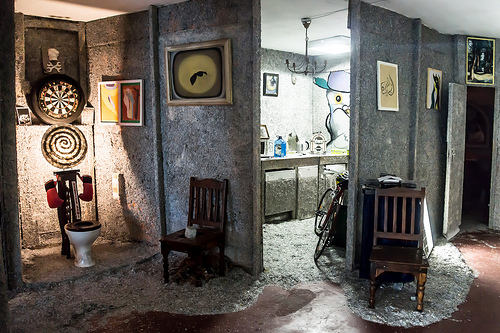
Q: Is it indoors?
A: Yes, it is indoors.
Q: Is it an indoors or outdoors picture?
A: It is indoors.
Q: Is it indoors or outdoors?
A: It is indoors.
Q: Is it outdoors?
A: No, it is indoors.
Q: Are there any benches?
A: No, there are no benches.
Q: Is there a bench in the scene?
A: No, there are no benches.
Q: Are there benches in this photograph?
A: No, there are no benches.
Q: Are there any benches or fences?
A: No, there are no benches or fences.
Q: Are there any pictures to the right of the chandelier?
A: Yes, there is a picture to the right of the chandelier.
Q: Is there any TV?
A: No, there are no televisions.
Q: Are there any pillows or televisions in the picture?
A: No, there are no televisions or pillows.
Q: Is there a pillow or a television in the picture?
A: No, there are no televisions or pillows.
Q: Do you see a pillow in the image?
A: No, there are no pillows.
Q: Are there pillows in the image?
A: No, there are no pillows.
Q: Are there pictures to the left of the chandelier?
A: Yes, there is a picture to the left of the chandelier.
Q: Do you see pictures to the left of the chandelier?
A: Yes, there is a picture to the left of the chandelier.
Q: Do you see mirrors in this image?
A: No, there are no mirrors.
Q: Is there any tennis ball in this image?
A: No, there are no tennis balls.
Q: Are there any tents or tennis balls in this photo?
A: No, there are no tennis balls or tents.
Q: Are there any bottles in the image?
A: Yes, there is a bottle.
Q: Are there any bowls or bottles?
A: Yes, there is a bottle.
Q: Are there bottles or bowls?
A: Yes, there is a bottle.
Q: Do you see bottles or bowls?
A: Yes, there is a bottle.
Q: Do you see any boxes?
A: No, there are no boxes.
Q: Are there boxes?
A: No, there are no boxes.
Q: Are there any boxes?
A: No, there are no boxes.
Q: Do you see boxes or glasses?
A: No, there are no boxes or glasses.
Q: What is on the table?
A: The bottle is on the table.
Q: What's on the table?
A: The bottle is on the table.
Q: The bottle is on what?
A: The bottle is on the table.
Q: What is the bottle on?
A: The bottle is on the table.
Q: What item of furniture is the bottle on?
A: The bottle is on the table.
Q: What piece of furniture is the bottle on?
A: The bottle is on the table.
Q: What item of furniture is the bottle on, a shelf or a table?
A: The bottle is on a table.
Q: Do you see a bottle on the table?
A: Yes, there is a bottle on the table.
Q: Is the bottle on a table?
A: Yes, the bottle is on a table.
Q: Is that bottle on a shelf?
A: No, the bottle is on a table.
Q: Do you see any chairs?
A: Yes, there is a chair.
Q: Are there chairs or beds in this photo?
A: Yes, there is a chair.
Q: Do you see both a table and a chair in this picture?
A: Yes, there are both a chair and a table.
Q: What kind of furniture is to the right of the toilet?
A: The piece of furniture is a chair.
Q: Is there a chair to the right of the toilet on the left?
A: Yes, there is a chair to the right of the toilet.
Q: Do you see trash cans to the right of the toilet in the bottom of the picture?
A: No, there is a chair to the right of the toilet.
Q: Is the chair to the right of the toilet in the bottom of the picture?
A: Yes, the chair is to the right of the toilet.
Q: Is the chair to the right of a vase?
A: No, the chair is to the right of the toilet.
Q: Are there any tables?
A: Yes, there is a table.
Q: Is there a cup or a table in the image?
A: Yes, there is a table.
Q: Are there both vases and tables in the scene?
A: No, there is a table but no vases.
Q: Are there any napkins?
A: No, there are no napkins.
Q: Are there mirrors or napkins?
A: No, there are no napkins or mirrors.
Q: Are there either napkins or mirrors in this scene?
A: No, there are no napkins or mirrors.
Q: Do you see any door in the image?
A: Yes, there is a door.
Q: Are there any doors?
A: Yes, there is a door.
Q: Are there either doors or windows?
A: Yes, there is a door.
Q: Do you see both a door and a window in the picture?
A: No, there is a door but no windows.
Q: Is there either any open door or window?
A: Yes, there is an open door.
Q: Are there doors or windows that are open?
A: Yes, the door is open.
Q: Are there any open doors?
A: Yes, there is an open door.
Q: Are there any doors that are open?
A: Yes, there is a door that is open.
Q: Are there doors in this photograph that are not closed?
A: Yes, there is a open door.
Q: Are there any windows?
A: No, there are no windows.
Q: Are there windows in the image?
A: No, there are no windows.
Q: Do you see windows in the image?
A: No, there are no windows.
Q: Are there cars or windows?
A: No, there are no windows or cars.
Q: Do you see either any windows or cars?
A: No, there are no windows or cars.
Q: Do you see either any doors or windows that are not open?
A: No, there is a door but it is open.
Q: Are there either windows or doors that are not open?
A: No, there is a door but it is open.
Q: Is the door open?
A: Yes, the door is open.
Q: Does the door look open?
A: Yes, the door is open.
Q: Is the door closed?
A: No, the door is open.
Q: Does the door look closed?
A: No, the door is open.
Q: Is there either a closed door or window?
A: No, there is a door but it is open.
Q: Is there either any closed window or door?
A: No, there is a door but it is open.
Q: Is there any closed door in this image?
A: No, there is a door but it is open.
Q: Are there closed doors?
A: No, there is a door but it is open.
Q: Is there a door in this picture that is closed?
A: No, there is a door but it is open.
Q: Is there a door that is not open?
A: No, there is a door but it is open.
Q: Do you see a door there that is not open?
A: No, there is a door but it is open.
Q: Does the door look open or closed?
A: The door is open.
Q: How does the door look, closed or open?
A: The door is open.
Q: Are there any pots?
A: No, there are no pots.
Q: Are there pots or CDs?
A: No, there are no pots or cds.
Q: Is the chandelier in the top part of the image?
A: Yes, the chandelier is in the top of the image.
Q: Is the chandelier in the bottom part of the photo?
A: No, the chandelier is in the top of the image.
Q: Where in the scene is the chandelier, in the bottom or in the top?
A: The chandelier is in the top of the image.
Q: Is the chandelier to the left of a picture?
A: Yes, the chandelier is to the left of a picture.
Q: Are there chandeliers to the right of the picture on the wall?
A: Yes, there is a chandelier to the right of the picture.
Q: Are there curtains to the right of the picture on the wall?
A: No, there is a chandelier to the right of the picture.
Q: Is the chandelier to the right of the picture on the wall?
A: Yes, the chandelier is to the right of the picture.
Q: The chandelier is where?
A: The chandelier is in the kitchen.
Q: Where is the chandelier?
A: The chandelier is in the kitchen.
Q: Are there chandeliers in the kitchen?
A: Yes, there is a chandelier in the kitchen.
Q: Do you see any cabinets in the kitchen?
A: No, there is a chandelier in the kitchen.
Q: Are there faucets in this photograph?
A: No, there are no faucets.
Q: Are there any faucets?
A: No, there are no faucets.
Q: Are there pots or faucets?
A: No, there are no faucets or pots.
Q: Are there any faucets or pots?
A: No, there are no faucets or pots.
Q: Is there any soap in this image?
A: No, there are no soaps.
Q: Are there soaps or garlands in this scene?
A: No, there are no soaps or garlands.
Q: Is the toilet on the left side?
A: Yes, the toilet is on the left of the image.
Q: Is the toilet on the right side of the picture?
A: No, the toilet is on the left of the image.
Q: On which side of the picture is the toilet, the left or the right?
A: The toilet is on the left of the image.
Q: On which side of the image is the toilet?
A: The toilet is on the left of the image.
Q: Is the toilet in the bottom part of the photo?
A: Yes, the toilet is in the bottom of the image.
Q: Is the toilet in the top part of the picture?
A: No, the toilet is in the bottom of the image.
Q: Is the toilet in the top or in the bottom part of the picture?
A: The toilet is in the bottom of the image.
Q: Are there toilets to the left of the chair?
A: Yes, there is a toilet to the left of the chair.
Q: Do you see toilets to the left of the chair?
A: Yes, there is a toilet to the left of the chair.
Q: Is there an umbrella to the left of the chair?
A: No, there is a toilet to the left of the chair.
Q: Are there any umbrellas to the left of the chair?
A: No, there is a toilet to the left of the chair.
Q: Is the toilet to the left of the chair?
A: Yes, the toilet is to the left of the chair.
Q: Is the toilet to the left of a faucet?
A: No, the toilet is to the left of the chair.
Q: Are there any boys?
A: No, there are no boys.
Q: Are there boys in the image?
A: No, there are no boys.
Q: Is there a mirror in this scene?
A: No, there are no mirrors.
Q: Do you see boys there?
A: No, there are no boys.